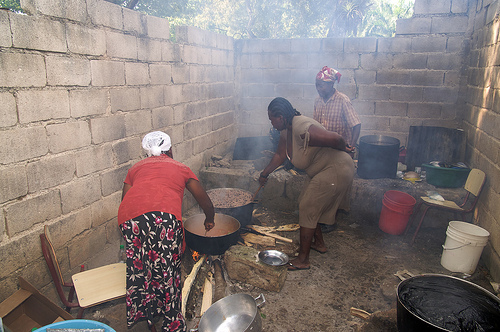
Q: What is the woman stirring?
A: A large kettle.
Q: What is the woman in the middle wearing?
A: A tan outfit.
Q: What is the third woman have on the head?
A: A scarf.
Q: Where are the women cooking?
A: In a building.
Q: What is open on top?
A: A building.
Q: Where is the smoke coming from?
A: A wood store.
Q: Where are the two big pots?
A: On a wood stove.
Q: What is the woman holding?
A: A utensil.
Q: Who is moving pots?
A: A woman.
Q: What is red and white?
A: The kitchen pails.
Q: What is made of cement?
A: The wall.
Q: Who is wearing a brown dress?
A: A woman.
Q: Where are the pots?
A: Over a fire.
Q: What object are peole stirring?
A: Food.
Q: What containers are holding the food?
A: Pots.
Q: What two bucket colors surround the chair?
A: Red and white.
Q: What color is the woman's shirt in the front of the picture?
A: Red.